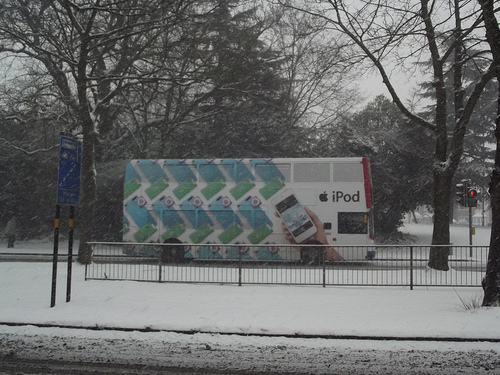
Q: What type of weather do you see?
A: It is cloudy.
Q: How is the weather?
A: It is cloudy.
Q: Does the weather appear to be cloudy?
A: Yes, it is cloudy.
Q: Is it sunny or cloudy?
A: It is cloudy.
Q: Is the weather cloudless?
A: No, it is cloudy.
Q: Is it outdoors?
A: Yes, it is outdoors.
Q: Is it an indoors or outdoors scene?
A: It is outdoors.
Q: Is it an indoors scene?
A: No, it is outdoors.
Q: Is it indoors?
A: No, it is outdoors.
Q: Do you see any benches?
A: No, there are no benches.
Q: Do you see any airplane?
A: No, there are no airplanes.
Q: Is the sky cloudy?
A: Yes, the sky is cloudy.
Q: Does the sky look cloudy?
A: Yes, the sky is cloudy.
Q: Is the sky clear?
A: No, the sky is cloudy.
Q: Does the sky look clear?
A: No, the sky is cloudy.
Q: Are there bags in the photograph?
A: No, there are no bags.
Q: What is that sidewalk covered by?
A: The sidewalk is covered by the snow.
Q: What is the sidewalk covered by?
A: The sidewalk is covered by the snow.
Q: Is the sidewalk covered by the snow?
A: Yes, the sidewalk is covered by the snow.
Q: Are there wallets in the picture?
A: No, there are no wallets.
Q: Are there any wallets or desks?
A: No, there are no wallets or desks.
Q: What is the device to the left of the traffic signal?
A: The device is an ipod.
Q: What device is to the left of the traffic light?
A: The device is an ipod.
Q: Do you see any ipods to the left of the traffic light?
A: Yes, there is an ipod to the left of the traffic light.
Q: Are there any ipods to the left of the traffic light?
A: Yes, there is an ipod to the left of the traffic light.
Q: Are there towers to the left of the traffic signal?
A: No, there is an ipod to the left of the traffic signal.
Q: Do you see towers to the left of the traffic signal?
A: No, there is an ipod to the left of the traffic signal.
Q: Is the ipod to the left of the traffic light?
A: Yes, the ipod is to the left of the traffic light.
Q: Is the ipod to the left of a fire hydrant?
A: No, the ipod is to the left of the traffic light.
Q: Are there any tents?
A: No, there are no tents.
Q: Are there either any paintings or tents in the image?
A: No, there are no tents or paintings.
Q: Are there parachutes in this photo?
A: No, there are no parachutes.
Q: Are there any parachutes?
A: No, there are no parachutes.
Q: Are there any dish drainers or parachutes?
A: No, there are no parachutes or dish drainers.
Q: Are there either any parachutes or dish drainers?
A: No, there are no parachutes or dish drainers.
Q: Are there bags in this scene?
A: No, there are no bags.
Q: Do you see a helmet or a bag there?
A: No, there are no bags or helmets.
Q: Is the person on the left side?
A: Yes, the person is on the left of the image.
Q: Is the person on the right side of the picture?
A: No, the person is on the left of the image.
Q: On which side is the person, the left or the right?
A: The person is on the left of the image.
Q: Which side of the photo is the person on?
A: The person is on the left of the image.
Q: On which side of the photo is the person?
A: The person is on the left of the image.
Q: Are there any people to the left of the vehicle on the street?
A: Yes, there is a person to the left of the vehicle.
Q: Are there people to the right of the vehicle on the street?
A: No, the person is to the left of the vehicle.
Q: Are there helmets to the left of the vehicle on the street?
A: No, there is a person to the left of the vehicle.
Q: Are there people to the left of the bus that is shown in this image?
A: Yes, there is a person to the left of the bus.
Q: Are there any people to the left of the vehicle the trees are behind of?
A: Yes, there is a person to the left of the bus.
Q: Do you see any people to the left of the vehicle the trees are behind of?
A: Yes, there is a person to the left of the bus.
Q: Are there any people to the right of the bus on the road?
A: No, the person is to the left of the bus.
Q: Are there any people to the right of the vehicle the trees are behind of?
A: No, the person is to the left of the bus.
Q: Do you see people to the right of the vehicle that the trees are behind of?
A: No, the person is to the left of the bus.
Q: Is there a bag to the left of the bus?
A: No, there is a person to the left of the bus.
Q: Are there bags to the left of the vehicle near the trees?
A: No, there is a person to the left of the bus.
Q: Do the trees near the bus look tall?
A: Yes, the trees are tall.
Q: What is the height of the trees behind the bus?
A: The trees are tall.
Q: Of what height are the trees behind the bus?
A: The trees are tall.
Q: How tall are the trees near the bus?
A: The trees are tall.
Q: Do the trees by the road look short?
A: No, the trees are tall.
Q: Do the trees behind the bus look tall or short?
A: The trees are tall.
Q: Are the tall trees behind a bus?
A: Yes, the trees are behind a bus.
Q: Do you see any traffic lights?
A: Yes, there is a traffic light.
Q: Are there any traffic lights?
A: Yes, there is a traffic light.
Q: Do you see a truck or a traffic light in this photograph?
A: Yes, there is a traffic light.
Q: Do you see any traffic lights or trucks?
A: Yes, there is a traffic light.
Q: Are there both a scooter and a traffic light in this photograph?
A: No, there is a traffic light but no scooters.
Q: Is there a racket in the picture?
A: No, there are no rackets.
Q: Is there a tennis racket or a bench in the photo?
A: No, there are no rackets or benches.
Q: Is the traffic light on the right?
A: Yes, the traffic light is on the right of the image.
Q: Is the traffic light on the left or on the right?
A: The traffic light is on the right of the image.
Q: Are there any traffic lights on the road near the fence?
A: Yes, there is a traffic light on the road.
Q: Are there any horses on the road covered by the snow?
A: No, there is a traffic light on the road.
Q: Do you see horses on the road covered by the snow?
A: No, there is a traffic light on the road.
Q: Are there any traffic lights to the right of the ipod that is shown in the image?
A: Yes, there is a traffic light to the right of the ipod.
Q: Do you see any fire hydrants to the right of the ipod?
A: No, there is a traffic light to the right of the ipod.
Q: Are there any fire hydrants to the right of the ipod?
A: No, there is a traffic light to the right of the ipod.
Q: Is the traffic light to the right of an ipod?
A: Yes, the traffic light is to the right of an ipod.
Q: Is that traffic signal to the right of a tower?
A: No, the traffic signal is to the right of an ipod.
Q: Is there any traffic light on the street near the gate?
A: Yes, there is a traffic light on the street.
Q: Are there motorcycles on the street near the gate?
A: No, there is a traffic light on the street.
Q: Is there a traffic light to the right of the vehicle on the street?
A: Yes, there is a traffic light to the right of the vehicle.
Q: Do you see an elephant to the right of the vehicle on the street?
A: No, there is a traffic light to the right of the vehicle.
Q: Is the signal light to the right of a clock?
A: No, the signal light is to the right of the vehicle.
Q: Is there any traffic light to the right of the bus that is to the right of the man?
A: Yes, there is a traffic light to the right of the bus.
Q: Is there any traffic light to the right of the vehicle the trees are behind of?
A: Yes, there is a traffic light to the right of the bus.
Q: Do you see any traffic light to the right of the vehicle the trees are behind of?
A: Yes, there is a traffic light to the right of the bus.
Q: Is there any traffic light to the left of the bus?
A: No, the traffic light is to the right of the bus.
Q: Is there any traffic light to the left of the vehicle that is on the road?
A: No, the traffic light is to the right of the bus.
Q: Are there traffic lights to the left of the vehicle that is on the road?
A: No, the traffic light is to the right of the bus.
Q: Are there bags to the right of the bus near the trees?
A: No, there is a traffic light to the right of the bus.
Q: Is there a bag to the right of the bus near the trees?
A: No, there is a traffic light to the right of the bus.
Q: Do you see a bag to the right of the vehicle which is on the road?
A: No, there is a traffic light to the right of the bus.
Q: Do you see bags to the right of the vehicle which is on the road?
A: No, there is a traffic light to the right of the bus.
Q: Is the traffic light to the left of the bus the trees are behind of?
A: No, the traffic light is to the right of the bus.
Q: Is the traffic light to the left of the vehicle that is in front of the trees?
A: No, the traffic light is to the right of the bus.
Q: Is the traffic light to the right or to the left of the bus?
A: The traffic light is to the right of the bus.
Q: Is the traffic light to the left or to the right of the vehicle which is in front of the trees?
A: The traffic light is to the right of the bus.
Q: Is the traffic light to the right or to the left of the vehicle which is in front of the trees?
A: The traffic light is to the right of the bus.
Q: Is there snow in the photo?
A: Yes, there is snow.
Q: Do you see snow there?
A: Yes, there is snow.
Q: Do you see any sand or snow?
A: Yes, there is snow.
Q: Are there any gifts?
A: No, there are no gifts.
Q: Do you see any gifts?
A: No, there are no gifts.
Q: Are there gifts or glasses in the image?
A: No, there are no gifts or glasses.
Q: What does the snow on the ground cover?
A: The snow covers the road.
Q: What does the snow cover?
A: The snow covers the road.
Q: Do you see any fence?
A: Yes, there is a fence.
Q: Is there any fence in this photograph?
A: Yes, there is a fence.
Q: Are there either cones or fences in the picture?
A: Yes, there is a fence.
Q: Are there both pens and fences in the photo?
A: No, there is a fence but no pens.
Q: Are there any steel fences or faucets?
A: Yes, there is a steel fence.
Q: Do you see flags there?
A: No, there are no flags.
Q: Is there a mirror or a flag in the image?
A: No, there are no flags or mirrors.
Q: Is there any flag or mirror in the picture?
A: No, there are no flags or mirrors.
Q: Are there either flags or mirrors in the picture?
A: No, there are no flags or mirrors.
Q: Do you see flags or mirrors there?
A: No, there are no flags or mirrors.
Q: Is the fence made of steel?
A: Yes, the fence is made of steel.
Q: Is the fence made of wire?
A: No, the fence is made of steel.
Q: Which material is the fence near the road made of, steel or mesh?
A: The fence is made of steel.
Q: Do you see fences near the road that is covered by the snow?
A: Yes, there is a fence near the road.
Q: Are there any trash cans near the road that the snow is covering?
A: No, there is a fence near the road.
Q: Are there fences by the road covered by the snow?
A: Yes, there is a fence by the road.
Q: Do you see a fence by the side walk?
A: Yes, there is a fence by the side walk.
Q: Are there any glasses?
A: No, there are no glasses.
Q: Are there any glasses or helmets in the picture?
A: No, there are no glasses or helmets.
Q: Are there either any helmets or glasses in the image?
A: No, there are no glasses or helmets.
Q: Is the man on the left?
A: Yes, the man is on the left of the image.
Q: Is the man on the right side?
A: No, the man is on the left of the image.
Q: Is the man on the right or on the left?
A: The man is on the left of the image.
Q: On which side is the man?
A: The man is on the left of the image.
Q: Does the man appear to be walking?
A: Yes, the man is walking.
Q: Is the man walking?
A: Yes, the man is walking.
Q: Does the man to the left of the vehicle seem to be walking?
A: Yes, the man is walking.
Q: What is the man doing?
A: The man is walking.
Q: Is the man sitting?
A: No, the man is walking.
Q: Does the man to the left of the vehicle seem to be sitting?
A: No, the man is walking.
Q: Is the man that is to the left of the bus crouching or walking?
A: The man is walking.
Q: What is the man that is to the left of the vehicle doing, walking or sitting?
A: The man is walking.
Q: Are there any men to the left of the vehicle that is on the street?
A: Yes, there is a man to the left of the vehicle.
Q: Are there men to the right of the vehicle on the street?
A: No, the man is to the left of the vehicle.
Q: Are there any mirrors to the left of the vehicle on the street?
A: No, there is a man to the left of the vehicle.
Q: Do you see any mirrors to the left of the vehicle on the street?
A: No, there is a man to the left of the vehicle.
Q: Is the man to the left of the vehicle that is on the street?
A: Yes, the man is to the left of the vehicle.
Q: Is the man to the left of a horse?
A: No, the man is to the left of the vehicle.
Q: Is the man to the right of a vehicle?
A: No, the man is to the left of a vehicle.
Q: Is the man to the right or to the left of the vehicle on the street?
A: The man is to the left of the vehicle.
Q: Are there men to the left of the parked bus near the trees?
A: Yes, there is a man to the left of the bus.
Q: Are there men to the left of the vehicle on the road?
A: Yes, there is a man to the left of the bus.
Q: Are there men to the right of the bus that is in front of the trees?
A: No, the man is to the left of the bus.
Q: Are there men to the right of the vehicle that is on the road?
A: No, the man is to the left of the bus.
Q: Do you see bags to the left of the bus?
A: No, there is a man to the left of the bus.